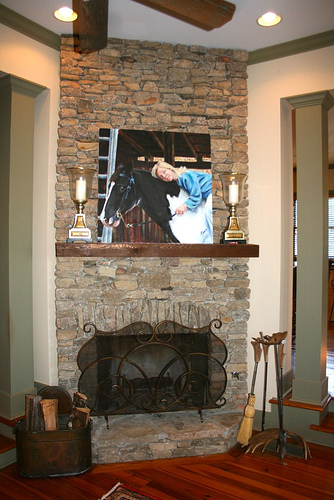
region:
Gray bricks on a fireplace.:
[88, 67, 228, 111]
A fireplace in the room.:
[54, 41, 258, 460]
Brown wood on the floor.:
[182, 469, 311, 492]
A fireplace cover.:
[62, 305, 229, 414]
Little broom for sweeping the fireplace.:
[224, 337, 265, 445]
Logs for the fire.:
[15, 386, 88, 426]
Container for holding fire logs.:
[9, 375, 96, 478]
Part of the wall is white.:
[256, 75, 273, 157]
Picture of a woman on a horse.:
[93, 124, 220, 242]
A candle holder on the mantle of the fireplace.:
[50, 155, 104, 245]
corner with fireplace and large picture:
[17, 18, 303, 460]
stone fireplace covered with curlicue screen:
[48, 257, 245, 460]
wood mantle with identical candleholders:
[41, 154, 268, 279]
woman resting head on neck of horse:
[89, 115, 209, 247]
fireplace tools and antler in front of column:
[228, 222, 319, 465]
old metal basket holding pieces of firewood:
[1, 366, 94, 484]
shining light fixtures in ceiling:
[28, 0, 301, 39]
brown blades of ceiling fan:
[57, 0, 250, 52]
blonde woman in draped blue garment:
[142, 153, 208, 216]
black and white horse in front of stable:
[93, 151, 192, 237]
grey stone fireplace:
[52, 257, 252, 456]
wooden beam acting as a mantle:
[52, 242, 264, 261]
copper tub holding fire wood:
[14, 381, 94, 481]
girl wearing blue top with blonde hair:
[148, 153, 210, 245]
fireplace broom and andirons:
[234, 328, 311, 458]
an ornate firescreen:
[74, 314, 226, 422]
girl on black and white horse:
[97, 144, 214, 243]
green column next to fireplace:
[281, 90, 333, 410]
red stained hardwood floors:
[16, 457, 332, 498]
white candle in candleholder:
[214, 163, 249, 245]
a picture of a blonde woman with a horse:
[104, 139, 206, 233]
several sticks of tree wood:
[24, 387, 86, 425]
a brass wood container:
[20, 426, 106, 476]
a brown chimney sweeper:
[242, 389, 254, 450]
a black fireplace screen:
[80, 339, 224, 405]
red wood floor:
[172, 463, 264, 495]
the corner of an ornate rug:
[105, 478, 145, 495]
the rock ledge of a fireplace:
[110, 428, 205, 453]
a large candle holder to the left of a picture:
[64, 162, 95, 241]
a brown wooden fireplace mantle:
[59, 239, 264, 264]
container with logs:
[6, 370, 97, 490]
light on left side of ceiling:
[50, 7, 80, 30]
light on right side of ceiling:
[250, 8, 283, 31]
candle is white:
[57, 154, 105, 251]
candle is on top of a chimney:
[211, 155, 254, 245]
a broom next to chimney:
[229, 341, 260, 449]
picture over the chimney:
[91, 116, 219, 246]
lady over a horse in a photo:
[143, 154, 225, 237]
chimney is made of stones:
[49, 45, 250, 452]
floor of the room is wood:
[52, 458, 324, 498]